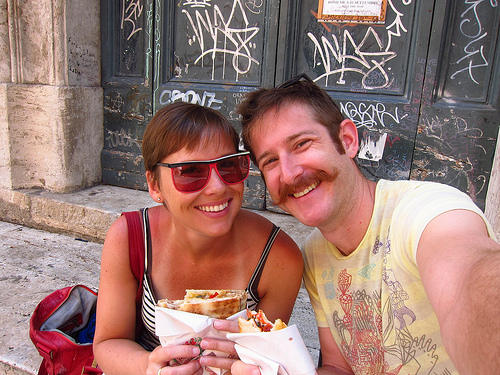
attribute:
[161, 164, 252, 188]
glasses — red, black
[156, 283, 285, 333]
food — inside of napkin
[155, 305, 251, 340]
napkin — holding food in woman's hands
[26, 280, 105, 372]
red bag — carried by woman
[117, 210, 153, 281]
strap — of the red bag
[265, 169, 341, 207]
mustache — on the man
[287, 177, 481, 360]
yellow shirt — on the man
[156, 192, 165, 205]
earring — on the woman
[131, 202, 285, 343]
white/black shirt — on the woman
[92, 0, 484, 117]
graffiti — on the door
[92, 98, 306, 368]
woman — wearing sunglasses, holding a sandwich, YOUNG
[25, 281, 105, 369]
bag — red, gray, and blue, sitting next to a woman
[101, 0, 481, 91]
black wall — with graffiti on it, in the background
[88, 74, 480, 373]
two people — sitting down, holding paninis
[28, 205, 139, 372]
red purse — on woman's shoulder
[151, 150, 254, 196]
woman — with red sunglasses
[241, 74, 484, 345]
man — holding a sandwich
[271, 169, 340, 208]
mustache — BROWN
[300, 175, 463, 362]
shirt — YELLOW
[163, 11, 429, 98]
door — BLACK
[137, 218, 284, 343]
tank top — BLACK, WHITE, STRIPE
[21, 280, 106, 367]
purse — OPENED, RED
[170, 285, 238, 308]
wrapper — WHITE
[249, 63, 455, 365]
man — YOUNG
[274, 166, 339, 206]
mustache — PROMINENT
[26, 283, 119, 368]
bag — OPEN, RED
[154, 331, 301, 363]
paper — WHITE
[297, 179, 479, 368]
shirt — YELLOW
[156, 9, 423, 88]
doors — LARGE, BLACK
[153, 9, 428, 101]
doors — BLACK, LARGE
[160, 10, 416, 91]
graffiti — WHITE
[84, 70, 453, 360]
couple — SMILING PEOPLE, YOUNG